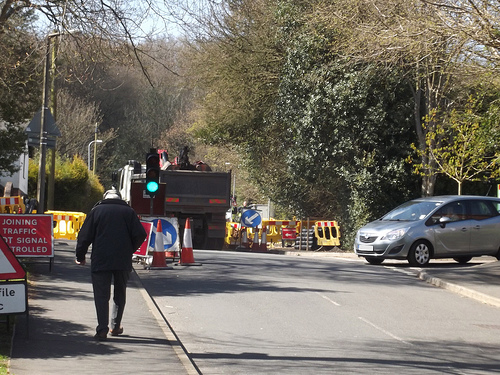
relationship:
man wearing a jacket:
[71, 182, 149, 356] [72, 193, 150, 281]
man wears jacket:
[74, 189, 148, 341] [73, 198, 148, 273]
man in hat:
[74, 189, 148, 341] [101, 187, 119, 198]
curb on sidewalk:
[400, 261, 499, 318] [425, 238, 497, 300]